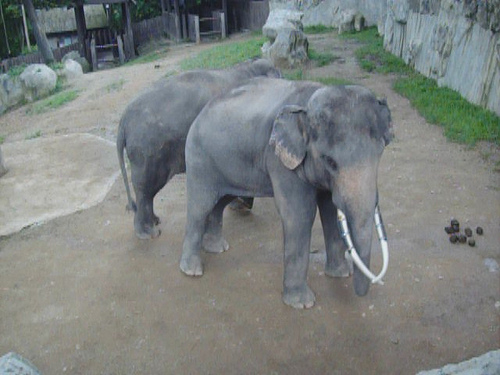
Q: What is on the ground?
A: Dirt.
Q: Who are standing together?
A: Elephants.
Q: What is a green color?
A: Grass.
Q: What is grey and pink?
A: Elephant ear.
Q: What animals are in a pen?
A: Elephants.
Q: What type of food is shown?
A: Elephants.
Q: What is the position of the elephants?
A: Standing.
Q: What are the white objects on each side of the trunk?
A: Tusks.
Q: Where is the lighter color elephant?
A: On the right.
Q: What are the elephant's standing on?
A: The ground.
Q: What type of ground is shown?
A: Bare.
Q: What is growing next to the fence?
A: Grass.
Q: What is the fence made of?
A: Wood.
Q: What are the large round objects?
A: Rocks.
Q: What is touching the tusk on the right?
A: The tusk on the left.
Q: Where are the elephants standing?
A: In the dirt.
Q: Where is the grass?
A: Beside the wall.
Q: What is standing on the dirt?
A: Two elephants.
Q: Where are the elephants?
A: In the pen.